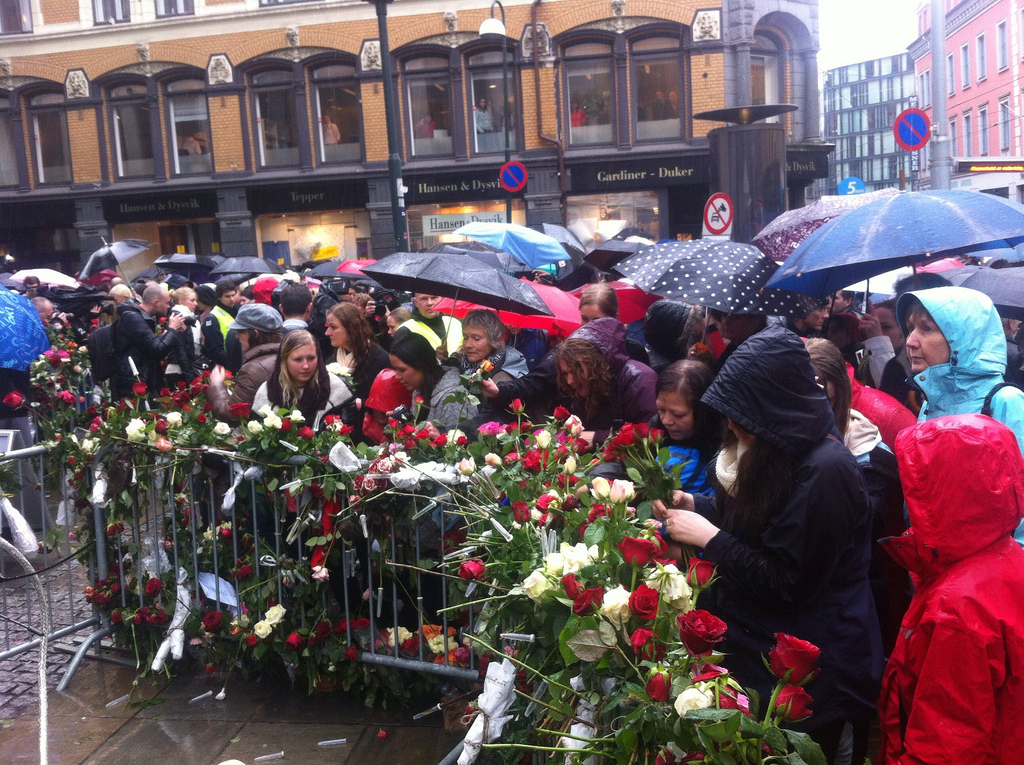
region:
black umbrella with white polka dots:
[612, 237, 810, 317]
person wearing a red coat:
[868, 402, 1020, 761]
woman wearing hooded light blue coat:
[890, 282, 1021, 545]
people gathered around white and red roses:
[5, 187, 1021, 760]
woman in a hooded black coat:
[662, 319, 885, 762]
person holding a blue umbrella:
[765, 184, 1022, 409]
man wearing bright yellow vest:
[362, 287, 470, 367]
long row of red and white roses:
[0, 306, 826, 762]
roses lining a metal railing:
[4, 310, 834, 760]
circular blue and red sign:
[491, 154, 531, 196]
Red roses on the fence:
[207, 377, 647, 741]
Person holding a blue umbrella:
[364, 190, 606, 435]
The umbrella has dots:
[610, 179, 836, 414]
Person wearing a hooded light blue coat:
[848, 255, 1020, 487]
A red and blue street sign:
[851, 83, 989, 268]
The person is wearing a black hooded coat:
[645, 290, 925, 711]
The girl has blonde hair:
[229, 284, 422, 501]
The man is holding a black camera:
[95, 255, 269, 421]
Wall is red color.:
[21, 23, 720, 205]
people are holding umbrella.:
[206, 170, 1007, 377]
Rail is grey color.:
[73, 447, 450, 672]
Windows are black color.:
[10, 23, 701, 239]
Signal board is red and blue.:
[878, 105, 948, 154]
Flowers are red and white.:
[129, 381, 774, 743]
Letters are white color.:
[391, 160, 708, 206]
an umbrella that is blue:
[803, 178, 977, 297]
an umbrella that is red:
[501, 271, 603, 335]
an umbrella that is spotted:
[634, 222, 775, 327]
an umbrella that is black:
[373, 241, 528, 319]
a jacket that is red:
[849, 423, 1021, 733]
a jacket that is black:
[684, 336, 877, 698]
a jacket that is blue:
[890, 274, 1017, 437]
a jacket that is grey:
[414, 366, 478, 427]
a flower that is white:
[532, 542, 600, 597]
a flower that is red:
[670, 597, 724, 662]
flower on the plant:
[618, 666, 685, 714]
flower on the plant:
[649, 664, 757, 706]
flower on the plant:
[533, 556, 588, 605]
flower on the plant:
[620, 499, 672, 567]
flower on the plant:
[411, 631, 460, 670]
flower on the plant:
[384, 440, 467, 475]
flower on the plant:
[206, 417, 292, 465]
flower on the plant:
[472, 497, 526, 596]